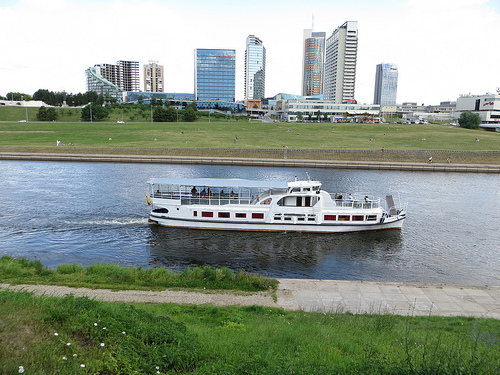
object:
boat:
[142, 178, 407, 235]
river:
[0, 156, 497, 284]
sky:
[1, 0, 499, 101]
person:
[191, 186, 197, 196]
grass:
[0, 258, 271, 289]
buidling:
[242, 35, 265, 105]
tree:
[153, 97, 167, 121]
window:
[324, 215, 336, 220]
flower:
[99, 342, 105, 347]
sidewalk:
[0, 268, 494, 319]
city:
[18, 19, 498, 122]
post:
[89, 103, 93, 123]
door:
[297, 197, 302, 206]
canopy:
[149, 178, 291, 189]